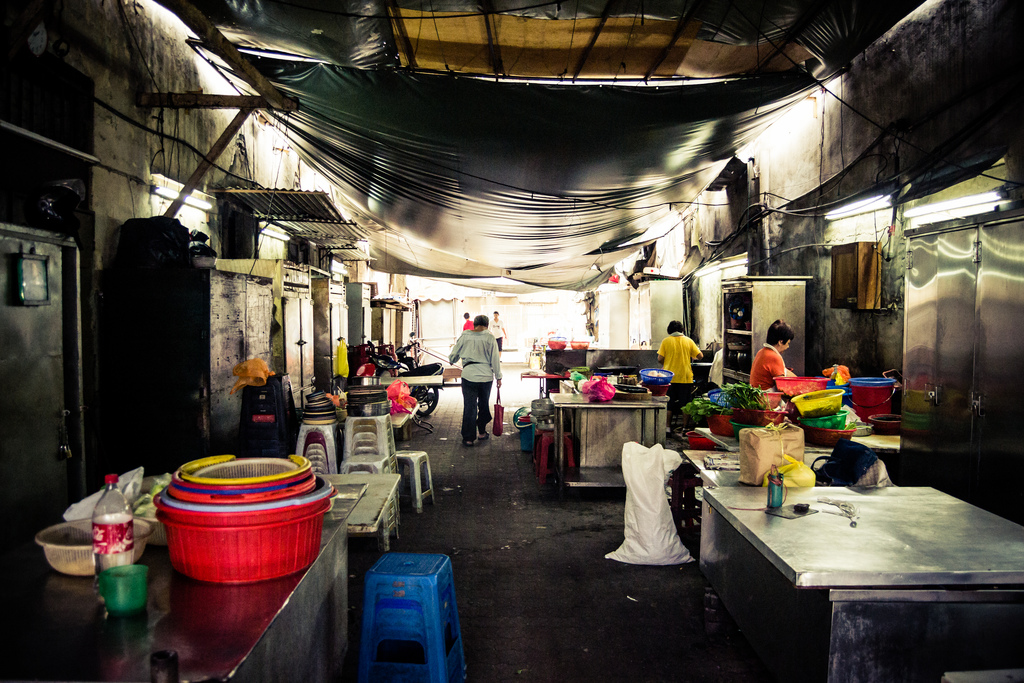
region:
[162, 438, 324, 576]
Stacked colorful bowls.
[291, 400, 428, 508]
White plastic stools.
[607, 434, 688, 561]
Large white bag.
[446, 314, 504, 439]
Person wearing long sleeved shirt and holding a bag.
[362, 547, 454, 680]
Plastic blue stools.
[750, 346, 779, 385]
the orange shirt of a woman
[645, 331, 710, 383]
the yellow shirt of a woman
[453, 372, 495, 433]
the legs of a woman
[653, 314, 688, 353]
the hair of a woman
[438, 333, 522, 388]
the blue shirt of a woman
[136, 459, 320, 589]
a bunch of plastic bowls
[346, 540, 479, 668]
a bunch of blue stools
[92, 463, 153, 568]
an empty plastic bottle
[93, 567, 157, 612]
a small green plastic cup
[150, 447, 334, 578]
Big colorful bowls stacked together.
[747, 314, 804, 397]
Woman wearing an orange shirt.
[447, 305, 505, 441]
Person carrying a red bag.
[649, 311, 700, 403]
Person wearing a yellow shirt working.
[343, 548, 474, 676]
Blue stool next to a large aluminum table.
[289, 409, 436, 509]
White stools stacked next to each other.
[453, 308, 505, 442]
Person wearing a white shirt and blue jeans walking.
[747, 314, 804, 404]
Woman surrounded by bowls working.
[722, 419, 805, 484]
Package wrapped in brown paper sitting on a table.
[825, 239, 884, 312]
Wooden cabinet underneath a white fluorescent light.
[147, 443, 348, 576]
A large colored bucket.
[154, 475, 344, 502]
A large colored bucket.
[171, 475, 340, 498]
A large colored bucket.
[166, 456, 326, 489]
A large colored bucket.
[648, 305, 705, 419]
A person is standing up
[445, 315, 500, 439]
A person is standing up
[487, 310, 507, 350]
A person is standing up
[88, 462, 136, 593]
soda bottle on the table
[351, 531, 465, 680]
blue stool near the table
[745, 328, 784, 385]
woman wearing a orange shirt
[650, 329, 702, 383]
woman wearing a yellow shirt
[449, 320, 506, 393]
woman wearing a white shirt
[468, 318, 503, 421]
a man in a white shirt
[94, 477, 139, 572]
a bottle on the counter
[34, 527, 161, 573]
a small bowl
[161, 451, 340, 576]
a stack of bowls on the counter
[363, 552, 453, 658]
a blue stool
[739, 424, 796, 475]
a bag on the counter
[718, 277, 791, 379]
a tall white dresser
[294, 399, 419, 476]
a stack of stools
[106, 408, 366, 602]
red baskets on table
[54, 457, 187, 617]
coca-cola bottle on table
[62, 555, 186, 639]
green cup on table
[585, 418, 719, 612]
white sack on floor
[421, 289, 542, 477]
man holding red bag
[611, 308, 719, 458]
man wearing yellow shirt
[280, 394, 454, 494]
white bar stools stacked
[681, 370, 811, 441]
vegetables in baskets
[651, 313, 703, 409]
Asian worker in a building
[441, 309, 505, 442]
worker walking in a building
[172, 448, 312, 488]
yellow bowl in a stack of bowls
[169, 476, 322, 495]
red bowl in a stack of bowls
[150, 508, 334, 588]
red bowl in a stack of bowls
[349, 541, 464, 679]
blue stackable stool in a building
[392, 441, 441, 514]
white stackable stool in building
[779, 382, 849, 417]
yellow bowl near asian worker